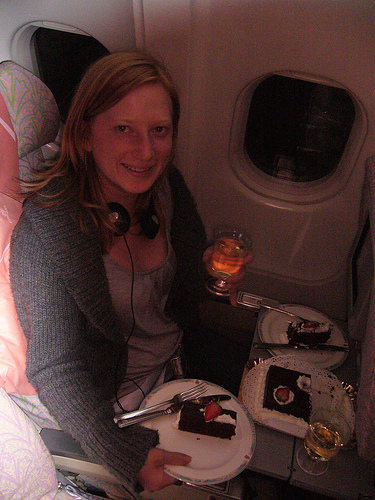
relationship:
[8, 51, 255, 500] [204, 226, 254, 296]
person holding glass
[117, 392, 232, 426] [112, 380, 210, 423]
knife next to fork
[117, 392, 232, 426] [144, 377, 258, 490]
knife on plate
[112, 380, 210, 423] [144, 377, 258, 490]
fork on plate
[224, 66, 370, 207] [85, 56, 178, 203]
window near head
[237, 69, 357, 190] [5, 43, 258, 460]
window in front of woman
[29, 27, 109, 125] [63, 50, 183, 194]
airplane window behind head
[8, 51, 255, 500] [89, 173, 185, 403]
person wearing shirt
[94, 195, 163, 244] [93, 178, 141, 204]
earphones around neck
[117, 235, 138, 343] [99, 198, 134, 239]
wire from earphones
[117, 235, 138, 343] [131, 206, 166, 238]
wire from earphones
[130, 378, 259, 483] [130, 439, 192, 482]
plate in hand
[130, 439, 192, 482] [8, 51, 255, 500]
hand of person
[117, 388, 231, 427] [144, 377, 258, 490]
butter knife on plate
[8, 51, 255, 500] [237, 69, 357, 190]
person next to window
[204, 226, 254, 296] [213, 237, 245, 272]
glass has liquid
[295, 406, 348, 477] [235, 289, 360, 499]
glass on tray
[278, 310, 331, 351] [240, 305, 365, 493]
desert on tray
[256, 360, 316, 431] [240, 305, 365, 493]
desert on tray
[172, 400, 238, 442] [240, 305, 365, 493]
desert on tray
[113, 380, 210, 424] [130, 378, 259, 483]
fork on plate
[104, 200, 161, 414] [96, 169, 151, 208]
earphones on neck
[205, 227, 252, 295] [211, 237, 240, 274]
glass has wine